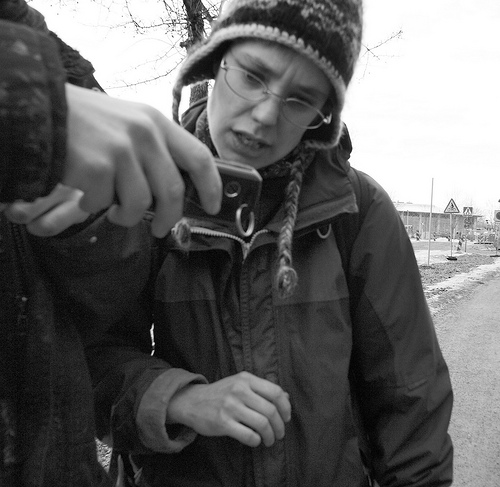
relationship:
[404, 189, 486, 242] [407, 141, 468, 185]
building in background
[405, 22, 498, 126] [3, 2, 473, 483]
sky above people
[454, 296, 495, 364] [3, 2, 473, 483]
road behind people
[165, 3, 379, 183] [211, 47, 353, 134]
woman looking down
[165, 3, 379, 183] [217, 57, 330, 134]
woman wearing glasses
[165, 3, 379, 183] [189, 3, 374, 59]
woman wearing warm hat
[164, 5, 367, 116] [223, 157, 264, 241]
person looking at phone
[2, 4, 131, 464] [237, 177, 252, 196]
person showing girl how to operate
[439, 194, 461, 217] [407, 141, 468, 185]
sign in background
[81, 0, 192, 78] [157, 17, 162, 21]
tree with no leaves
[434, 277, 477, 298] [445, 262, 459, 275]
parking strip with grass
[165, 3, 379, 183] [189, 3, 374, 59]
woman wearing hat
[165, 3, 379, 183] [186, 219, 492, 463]
woman wearing coat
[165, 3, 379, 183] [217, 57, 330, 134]
woman wearing eyeglasses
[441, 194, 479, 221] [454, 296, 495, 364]
signs in side of road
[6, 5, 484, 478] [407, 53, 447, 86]
picture in day time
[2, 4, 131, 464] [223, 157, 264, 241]
person holding mobile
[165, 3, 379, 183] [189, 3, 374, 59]
woman wearing cap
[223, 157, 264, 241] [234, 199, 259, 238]
cellphone has ring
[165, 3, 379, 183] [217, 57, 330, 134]
boy wearing glasses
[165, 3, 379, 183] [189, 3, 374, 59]
boy wearing hat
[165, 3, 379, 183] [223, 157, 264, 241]
boy looking at cellphone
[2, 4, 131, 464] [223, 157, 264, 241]
person holding cellphone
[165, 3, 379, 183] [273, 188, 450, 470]
boy wearing winter jacket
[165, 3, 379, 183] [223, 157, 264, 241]
boy watching cellphone screen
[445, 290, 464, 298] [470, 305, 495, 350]
dirt on ground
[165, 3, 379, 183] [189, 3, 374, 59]
child wearing winter hat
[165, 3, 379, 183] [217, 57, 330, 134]
child wearing glasses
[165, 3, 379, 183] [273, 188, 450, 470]
child wearing winter coat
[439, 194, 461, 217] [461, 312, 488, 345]
sign on street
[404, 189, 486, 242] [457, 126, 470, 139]
building in distance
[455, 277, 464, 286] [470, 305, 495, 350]
snow on ground